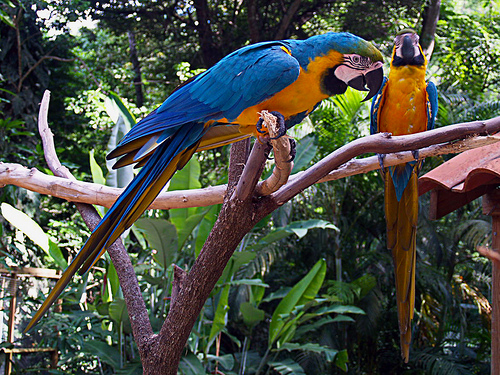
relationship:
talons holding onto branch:
[251, 108, 295, 162] [231, 92, 316, 208]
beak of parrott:
[331, 61, 384, 103] [50, 11, 395, 257]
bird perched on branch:
[21, 31, 383, 335] [235, 103, 295, 209]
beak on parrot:
[365, 69, 391, 98] [90, 26, 386, 178]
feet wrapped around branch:
[252, 109, 300, 156] [253, 110, 291, 192]